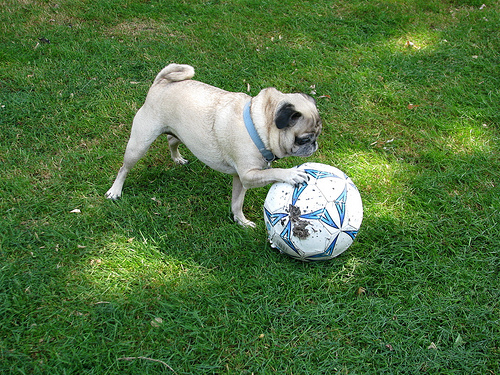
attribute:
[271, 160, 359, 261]
ball — white, blue, dirty, torn, gray, dirt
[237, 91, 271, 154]
collar — blue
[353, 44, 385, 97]
grass — yellow, green, short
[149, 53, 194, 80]
tail — curled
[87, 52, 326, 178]
dog — playing, white, brown, brow, black, small, plaful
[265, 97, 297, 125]
ear — black